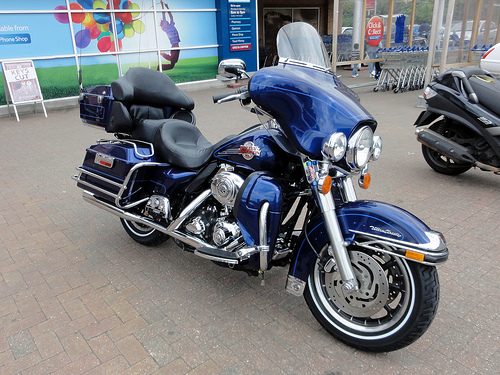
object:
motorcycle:
[69, 19, 451, 355]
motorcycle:
[410, 65, 498, 178]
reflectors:
[404, 249, 425, 262]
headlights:
[321, 123, 386, 171]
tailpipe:
[80, 188, 231, 250]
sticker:
[365, 15, 385, 48]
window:
[332, 0, 365, 63]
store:
[1, 0, 499, 116]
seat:
[108, 65, 240, 171]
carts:
[296, 45, 365, 94]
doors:
[261, 5, 293, 68]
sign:
[0, 59, 49, 124]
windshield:
[275, 20, 335, 72]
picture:
[1, 0, 219, 104]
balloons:
[73, 28, 92, 49]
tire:
[298, 234, 442, 353]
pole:
[437, 0, 457, 76]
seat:
[467, 72, 500, 118]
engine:
[181, 163, 249, 249]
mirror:
[216, 57, 247, 80]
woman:
[157, 2, 183, 74]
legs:
[12, 104, 22, 122]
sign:
[227, 1, 252, 51]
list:
[229, 37, 249, 44]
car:
[416, 106, 437, 143]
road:
[1, 118, 72, 373]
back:
[76, 83, 116, 128]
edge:
[403, 263, 418, 328]